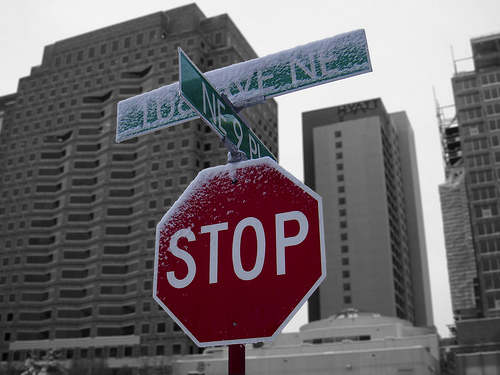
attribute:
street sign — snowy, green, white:
[115, 29, 373, 146]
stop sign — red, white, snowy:
[151, 155, 328, 350]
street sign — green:
[177, 46, 277, 163]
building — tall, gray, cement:
[301, 98, 417, 325]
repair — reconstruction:
[437, 43, 482, 321]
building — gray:
[430, 30, 498, 374]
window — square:
[333, 129, 342, 138]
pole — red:
[228, 151, 247, 375]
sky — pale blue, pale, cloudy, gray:
[1, 1, 500, 341]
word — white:
[166, 209, 308, 289]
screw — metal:
[222, 138, 249, 164]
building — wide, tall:
[0, 7, 279, 374]